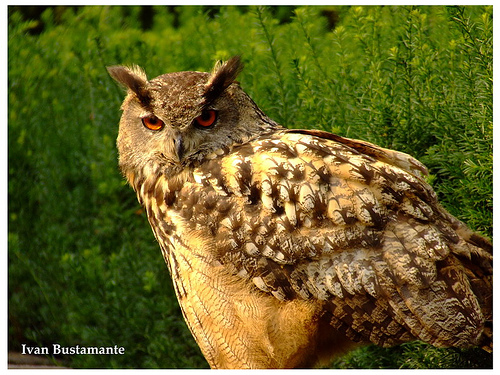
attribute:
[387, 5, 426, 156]
needles — green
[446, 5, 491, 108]
needles — green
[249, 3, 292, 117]
needles — green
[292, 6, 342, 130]
needles — green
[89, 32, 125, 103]
needles — green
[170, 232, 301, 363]
stomach — yellow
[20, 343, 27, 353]
letter — white , print style 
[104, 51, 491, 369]
owl — large, brown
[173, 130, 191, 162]
nose — small, black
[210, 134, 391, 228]
wing — patterned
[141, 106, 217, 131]
eyes — light brown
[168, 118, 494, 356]
feathers — dark, brown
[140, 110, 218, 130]
eyes — red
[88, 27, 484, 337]
owl — mad